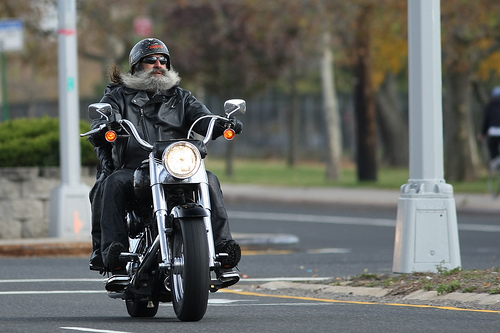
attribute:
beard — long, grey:
[116, 64, 181, 97]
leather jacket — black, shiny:
[86, 86, 233, 167]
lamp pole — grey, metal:
[393, 0, 461, 274]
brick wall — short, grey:
[1, 164, 98, 237]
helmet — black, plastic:
[126, 35, 172, 69]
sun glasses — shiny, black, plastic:
[140, 53, 167, 66]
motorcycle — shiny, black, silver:
[76, 92, 254, 324]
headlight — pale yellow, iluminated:
[159, 134, 206, 183]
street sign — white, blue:
[2, 16, 30, 55]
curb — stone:
[7, 233, 302, 260]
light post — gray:
[47, 5, 103, 246]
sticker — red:
[55, 26, 76, 39]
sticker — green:
[62, 77, 82, 93]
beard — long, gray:
[116, 67, 184, 95]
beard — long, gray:
[112, 69, 183, 94]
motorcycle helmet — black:
[127, 34, 174, 75]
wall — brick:
[2, 160, 105, 248]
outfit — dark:
[482, 97, 498, 160]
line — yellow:
[225, 283, 499, 323]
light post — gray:
[391, 0, 465, 275]